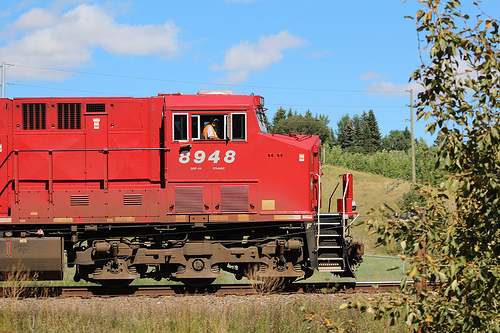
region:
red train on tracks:
[18, 70, 350, 258]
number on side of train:
[163, 133, 258, 173]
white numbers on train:
[142, 134, 242, 180]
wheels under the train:
[32, 220, 232, 295]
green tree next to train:
[340, 102, 390, 167]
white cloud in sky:
[232, 26, 297, 83]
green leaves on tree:
[365, 31, 495, 316]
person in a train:
[180, 95, 232, 151]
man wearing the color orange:
[190, 115, 225, 145]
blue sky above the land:
[330, 7, 371, 59]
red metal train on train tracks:
[2, 89, 364, 289]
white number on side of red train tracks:
[175, 146, 244, 170]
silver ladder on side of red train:
[312, 176, 351, 277]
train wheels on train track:
[67, 232, 306, 290]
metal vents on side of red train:
[64, 192, 147, 209]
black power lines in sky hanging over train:
[6, 60, 113, 97]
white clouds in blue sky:
[211, 18, 312, 75]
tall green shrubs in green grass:
[391, 3, 498, 332]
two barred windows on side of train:
[18, 101, 85, 132]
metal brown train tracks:
[363, 276, 402, 294]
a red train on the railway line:
[0, 91, 374, 327]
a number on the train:
[177, 145, 190, 165]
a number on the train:
[187, 147, 206, 172]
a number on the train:
[206, 146, 222, 170]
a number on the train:
[222, 147, 239, 171]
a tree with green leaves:
[373, 1, 498, 331]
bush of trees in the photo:
[275, 96, 435, 205]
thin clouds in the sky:
[0, 0, 305, 86]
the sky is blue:
[2, 1, 498, 149]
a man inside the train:
[199, 109, 226, 141]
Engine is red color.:
[23, 88, 328, 264]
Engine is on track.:
[41, 211, 476, 311]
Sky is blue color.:
[306, 20, 398, 60]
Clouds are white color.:
[11, 15, 137, 70]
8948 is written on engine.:
[171, 136, 252, 176]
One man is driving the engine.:
[180, 105, 240, 151]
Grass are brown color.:
[145, 296, 270, 328]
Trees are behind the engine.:
[270, 100, 432, 172]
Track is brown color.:
[305, 272, 425, 307]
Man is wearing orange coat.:
[190, 123, 232, 148]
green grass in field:
[362, 231, 392, 286]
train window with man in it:
[166, 110, 246, 155]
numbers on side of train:
[160, 145, 245, 176]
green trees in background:
[330, 95, 411, 175]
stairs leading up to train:
[305, 201, 351, 276]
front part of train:
[261, 122, 346, 229]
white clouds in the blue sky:
[22, 5, 310, 88]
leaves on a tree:
[393, 182, 490, 300]